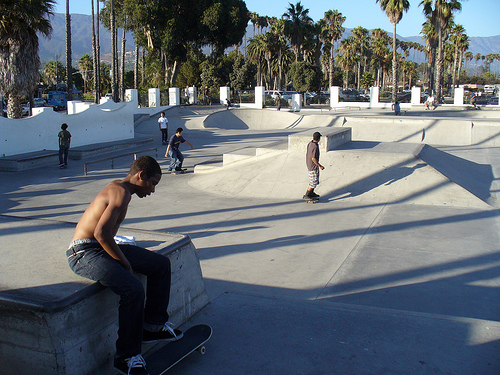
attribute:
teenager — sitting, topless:
[63, 150, 189, 374]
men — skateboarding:
[31, 107, 325, 374]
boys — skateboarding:
[55, 95, 325, 374]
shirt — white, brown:
[156, 114, 171, 132]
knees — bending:
[169, 152, 186, 162]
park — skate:
[2, 74, 497, 375]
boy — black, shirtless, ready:
[58, 150, 201, 375]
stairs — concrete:
[193, 123, 356, 180]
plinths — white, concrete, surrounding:
[109, 84, 477, 109]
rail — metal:
[80, 147, 160, 178]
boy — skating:
[294, 127, 325, 207]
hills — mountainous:
[2, 6, 500, 92]